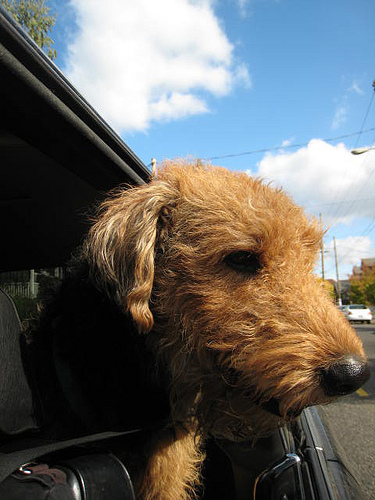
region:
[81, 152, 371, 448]
brown dog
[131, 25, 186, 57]
white clouds in blue sky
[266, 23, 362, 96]
white clouds in blue sky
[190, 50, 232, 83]
white clouds in blue sky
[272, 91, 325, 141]
white clouds in blue sky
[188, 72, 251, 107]
white clouds in blue sky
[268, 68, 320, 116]
white clouds in blue sky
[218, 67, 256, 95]
white clouds in blue sky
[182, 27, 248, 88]
white clouds in blue sky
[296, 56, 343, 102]
white clouds in blue sky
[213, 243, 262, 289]
The dogs right eye.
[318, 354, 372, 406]
The dogs nose.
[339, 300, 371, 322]
The white car in the street.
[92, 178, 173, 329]
The dogs right ear.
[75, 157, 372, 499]
A dog hanging out the window.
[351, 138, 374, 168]
The white light.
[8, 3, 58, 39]
The green trees.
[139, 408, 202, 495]
The dogs right leg.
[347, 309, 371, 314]
The lights on the back of the car.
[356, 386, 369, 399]
The yellow line on the road.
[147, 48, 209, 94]
white clouds in blue sky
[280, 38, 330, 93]
white clouds in blue sky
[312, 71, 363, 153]
white clouds in blue sky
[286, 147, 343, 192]
white clouds in blue sky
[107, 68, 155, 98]
white clouds in blue sky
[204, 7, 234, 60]
white clouds in blue sky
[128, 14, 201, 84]
white clouds in blue sky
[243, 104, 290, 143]
white clouds in blue sky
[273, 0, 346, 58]
white clouds in blue sky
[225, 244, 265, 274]
one eye of the dog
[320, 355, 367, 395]
the nose of the dog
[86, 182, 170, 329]
one ear of the dog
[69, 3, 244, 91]
a large white cloud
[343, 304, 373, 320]
a white car in the distance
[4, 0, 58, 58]
some tree leaves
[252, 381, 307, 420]
the mouth of the dog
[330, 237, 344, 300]
one electrical tower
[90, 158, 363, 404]
the head of the dog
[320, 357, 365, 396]
the nose of a dog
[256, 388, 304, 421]
the mouth of a dog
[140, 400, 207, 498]
the brown hairy leg of a dog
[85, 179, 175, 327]
the brown hairy ear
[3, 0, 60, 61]
the top of a green tree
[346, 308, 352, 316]
the red tail light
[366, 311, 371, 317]
the red tail light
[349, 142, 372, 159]
the white street light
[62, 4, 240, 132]
the big white cloud